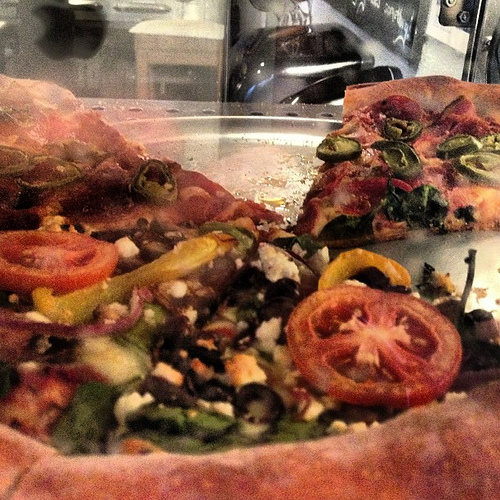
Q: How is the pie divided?
A: Into slices.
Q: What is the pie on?
A: A metal plate.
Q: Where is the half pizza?
A: On the tray.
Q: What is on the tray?
A: A piece of pizza.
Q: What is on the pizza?
A: A slice of a tomato.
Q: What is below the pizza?
A: A crust of a pizza.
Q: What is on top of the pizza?
A: The topping of a pizza.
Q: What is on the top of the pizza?
A: A piece of tomato.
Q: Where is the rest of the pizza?
A: On a pizza pan.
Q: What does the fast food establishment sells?
A: Pizza.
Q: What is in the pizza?
A: There are tomatoes.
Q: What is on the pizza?
A: Vegetables.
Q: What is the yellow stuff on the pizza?
A: Peppers.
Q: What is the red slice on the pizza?
A: Tomato.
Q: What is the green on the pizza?
A: Spinach.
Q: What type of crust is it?
A: Thick.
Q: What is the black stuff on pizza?
A: Olives.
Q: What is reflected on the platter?
A: Light.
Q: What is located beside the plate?
A: Window.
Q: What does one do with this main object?
A: Eat it.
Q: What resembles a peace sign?
A: Tomato.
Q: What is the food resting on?
A: Metal tray.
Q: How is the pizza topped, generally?
A: Generously.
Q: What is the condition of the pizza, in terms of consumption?
A: A little less than halfway eaten.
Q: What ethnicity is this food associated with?
A: Italian.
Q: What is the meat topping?
A: Pepperoni.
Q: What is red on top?
A: Tomato.